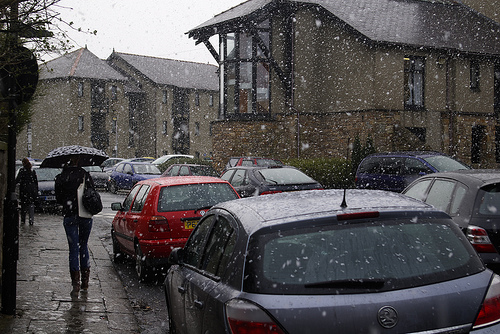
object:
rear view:
[239, 204, 483, 322]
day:
[0, 2, 491, 328]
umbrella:
[40, 145, 108, 169]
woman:
[53, 165, 103, 295]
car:
[115, 180, 229, 258]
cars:
[167, 183, 498, 334]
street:
[9, 142, 498, 332]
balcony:
[215, 30, 282, 123]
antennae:
[340, 144, 350, 208]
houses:
[192, 0, 498, 172]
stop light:
[2, 4, 42, 332]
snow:
[3, 1, 497, 317]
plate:
[184, 219, 199, 229]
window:
[216, 18, 271, 116]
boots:
[68, 269, 82, 296]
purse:
[82, 175, 101, 215]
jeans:
[62, 212, 93, 284]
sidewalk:
[12, 194, 130, 329]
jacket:
[55, 173, 95, 220]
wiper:
[304, 277, 383, 290]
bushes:
[193, 148, 375, 193]